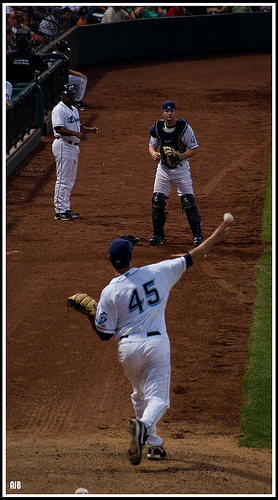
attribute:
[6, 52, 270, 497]
field — dirt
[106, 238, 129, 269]
hat — blue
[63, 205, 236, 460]
baseball player — warming up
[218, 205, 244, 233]
ball — mid-air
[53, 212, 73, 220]
shoe — black and white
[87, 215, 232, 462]
baseball player — throwing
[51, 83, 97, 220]
player — wearing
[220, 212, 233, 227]
baseball — thrown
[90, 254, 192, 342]
baseball jersey — white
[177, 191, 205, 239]
shin guards — black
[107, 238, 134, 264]
baseball hat — blue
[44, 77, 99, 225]
coach — watching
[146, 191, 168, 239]
shin guard — black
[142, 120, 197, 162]
gear — protective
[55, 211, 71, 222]
athletic shoe — black and white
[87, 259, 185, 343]
shirt — white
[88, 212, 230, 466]
player — throwing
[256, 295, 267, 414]
grass — green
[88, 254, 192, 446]
jersey — white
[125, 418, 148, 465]
shoe — black, white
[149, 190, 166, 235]
guard — knee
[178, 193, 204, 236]
guard — knee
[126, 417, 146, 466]
cleat — baseball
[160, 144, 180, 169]
glove — baseball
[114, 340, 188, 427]
pants — white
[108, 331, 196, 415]
pants — white